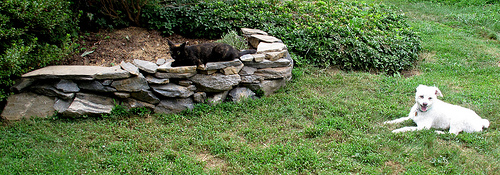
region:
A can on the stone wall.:
[162, 32, 262, 71]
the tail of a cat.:
[232, 44, 260, 60]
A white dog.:
[375, 76, 499, 156]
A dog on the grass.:
[369, 80, 499, 142]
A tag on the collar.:
[410, 109, 420, 120]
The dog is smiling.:
[412, 82, 444, 114]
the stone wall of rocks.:
[2, 64, 282, 124]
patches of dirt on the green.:
[143, 124, 343, 174]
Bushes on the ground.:
[287, 4, 427, 82]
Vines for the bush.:
[90, 0, 151, 30]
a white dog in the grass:
[386, 75, 495, 143]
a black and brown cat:
[146, 38, 250, 71]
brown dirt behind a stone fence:
[65, 27, 195, 56]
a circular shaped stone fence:
[9, 21, 302, 138]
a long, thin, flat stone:
[20, 61, 122, 83]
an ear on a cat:
[161, 37, 172, 47]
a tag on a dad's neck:
[412, 107, 422, 120]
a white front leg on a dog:
[388, 122, 424, 139]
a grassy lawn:
[0, 2, 497, 173]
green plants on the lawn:
[166, 2, 423, 72]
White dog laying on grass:
[393, 83, 493, 138]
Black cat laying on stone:
[167, 37, 242, 67]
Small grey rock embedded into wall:
[54, 78, 82, 94]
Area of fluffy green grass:
[221, 120, 325, 165]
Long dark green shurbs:
[324, 22, 419, 72]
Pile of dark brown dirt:
[103, 37, 155, 57]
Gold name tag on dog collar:
[411, 110, 419, 118]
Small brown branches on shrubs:
[100, 4, 144, 26]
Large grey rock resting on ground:
[1, 93, 59, 124]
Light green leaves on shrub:
[2, 35, 77, 63]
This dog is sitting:
[382, 74, 496, 152]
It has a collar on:
[391, 69, 491, 156]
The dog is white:
[382, 65, 499, 145]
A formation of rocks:
[8, 22, 346, 140]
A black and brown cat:
[151, 20, 269, 77]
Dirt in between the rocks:
[52, 12, 280, 87]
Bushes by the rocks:
[186, 4, 498, 92]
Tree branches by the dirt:
[63, 2, 210, 49]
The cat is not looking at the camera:
[136, 26, 301, 80]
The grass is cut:
[52, 93, 464, 173]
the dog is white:
[393, 85, 482, 146]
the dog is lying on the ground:
[401, 87, 482, 128]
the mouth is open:
[385, 90, 486, 140]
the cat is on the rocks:
[160, 35, 240, 55]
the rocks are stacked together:
[70, 65, 285, 100]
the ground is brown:
[111, 33, 161, 49]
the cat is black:
[156, 40, 241, 62]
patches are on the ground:
[185, 140, 245, 165]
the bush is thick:
[12, 0, 398, 70]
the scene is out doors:
[10, 9, 485, 174]